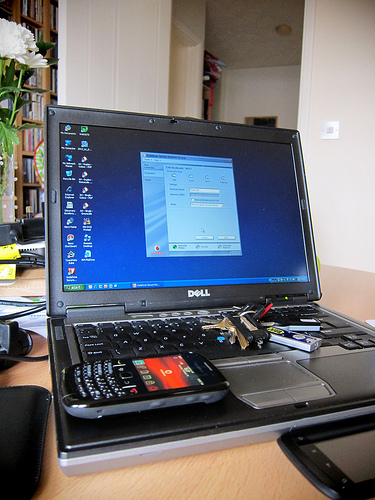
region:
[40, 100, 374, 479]
Open laptop on the desktop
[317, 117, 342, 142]
Light switch on the wall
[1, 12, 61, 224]
White floor in the vase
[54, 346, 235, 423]
Cell phone sitting on the laptop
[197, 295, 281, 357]
Set of keys sitting on the laptop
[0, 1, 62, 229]
Bookcase on the left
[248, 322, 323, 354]
Silver remote control on the laptop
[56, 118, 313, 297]
Blue screen on the laptop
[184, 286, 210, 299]
Del trademark on the laptop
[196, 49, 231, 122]
Open closet behind the laptop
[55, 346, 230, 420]
a black smart phone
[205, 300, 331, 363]
keys on top of a laptop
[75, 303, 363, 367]
the black keyboard of a laptop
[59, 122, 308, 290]
the blue screen of a laptop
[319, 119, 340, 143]
a thermostat on a wall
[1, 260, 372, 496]
a brown wood table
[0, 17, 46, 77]
a white flower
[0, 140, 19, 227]
a glass vase holding flowers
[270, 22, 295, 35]
a smoke detector on a ceiling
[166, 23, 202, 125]
a doorway behind a laptop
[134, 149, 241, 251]
a message on the computer screen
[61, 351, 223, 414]
a cellphone sitting on the laptop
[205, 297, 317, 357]
a pile of keys sitting on the keyboard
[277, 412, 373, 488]
Another cell phone sitting on the table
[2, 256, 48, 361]
some cords sitting on the the table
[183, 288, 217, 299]
the name of the computer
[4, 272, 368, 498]
the table everything is sitting on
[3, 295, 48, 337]
some papers under the cords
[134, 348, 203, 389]
the screen on the laptop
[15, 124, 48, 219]
a bookshelf in the background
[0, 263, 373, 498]
a wooden desk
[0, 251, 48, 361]
a group of wires on the desk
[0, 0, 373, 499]
the interior of an office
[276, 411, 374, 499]
a black smartphone on the desk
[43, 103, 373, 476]
a laptop computer on the desk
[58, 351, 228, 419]
a smartphone on the computer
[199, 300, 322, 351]
a group of keys on the computer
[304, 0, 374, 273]
a beige office wall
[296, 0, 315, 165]
the white trim of a doorway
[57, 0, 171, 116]
a white office door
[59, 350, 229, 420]
cellphone with keyboard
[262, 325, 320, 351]
keychain flashlight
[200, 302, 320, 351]
keychain with keys and flashlight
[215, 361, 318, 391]
grey laptop touchpad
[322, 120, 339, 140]
white plastic light switch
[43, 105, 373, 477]
dell laptop running MicroSoft windows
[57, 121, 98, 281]
desktop icons in Windows environment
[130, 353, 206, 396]
cellphone color screen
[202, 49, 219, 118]
shelves cluttered with books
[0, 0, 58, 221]
floor to ceiling bookshelf filled with books